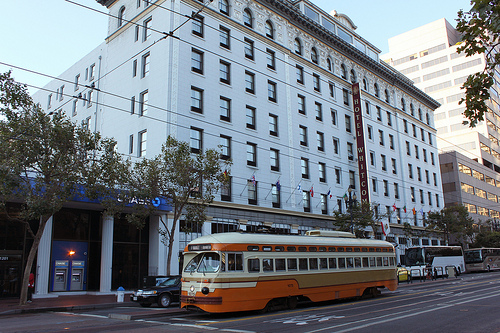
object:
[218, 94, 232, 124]
window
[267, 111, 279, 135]
window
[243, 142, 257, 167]
window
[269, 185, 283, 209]
window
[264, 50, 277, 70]
window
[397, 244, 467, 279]
bus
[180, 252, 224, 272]
windshield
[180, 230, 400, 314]
bus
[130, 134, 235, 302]
tree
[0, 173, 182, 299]
building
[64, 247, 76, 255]
light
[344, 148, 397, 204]
ground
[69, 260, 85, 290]
atm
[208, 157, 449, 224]
flags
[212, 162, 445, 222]
poles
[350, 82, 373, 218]
sign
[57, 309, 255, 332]
line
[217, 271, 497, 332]
lines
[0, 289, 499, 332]
floor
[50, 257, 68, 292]
atm machine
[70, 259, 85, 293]
atm machine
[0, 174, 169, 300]
chase bank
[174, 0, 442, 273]
building front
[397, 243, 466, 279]
tour bus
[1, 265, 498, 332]
road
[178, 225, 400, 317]
trolley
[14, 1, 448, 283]
building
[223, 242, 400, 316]
bus side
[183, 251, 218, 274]
window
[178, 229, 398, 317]
orange trolley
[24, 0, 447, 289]
hotel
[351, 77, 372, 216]
hotel sign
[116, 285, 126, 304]
fire hydrant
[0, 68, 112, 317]
tree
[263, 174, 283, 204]
flagpoles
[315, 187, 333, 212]
flagpoles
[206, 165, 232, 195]
flagpoles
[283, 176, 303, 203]
flagpoles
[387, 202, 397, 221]
flagpoles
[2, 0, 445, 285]
white building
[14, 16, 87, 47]
sky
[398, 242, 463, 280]
rails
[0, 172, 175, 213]
blue overhang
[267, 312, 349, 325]
instructions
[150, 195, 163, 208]
sign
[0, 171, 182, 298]
bank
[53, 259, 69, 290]
atm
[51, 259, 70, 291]
cash machine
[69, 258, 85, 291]
cash machine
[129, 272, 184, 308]
car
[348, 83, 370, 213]
lettering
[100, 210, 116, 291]
column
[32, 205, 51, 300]
column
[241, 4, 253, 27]
window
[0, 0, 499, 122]
top floor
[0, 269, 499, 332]
street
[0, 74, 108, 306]
tree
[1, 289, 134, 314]
sidewalk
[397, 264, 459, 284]
median